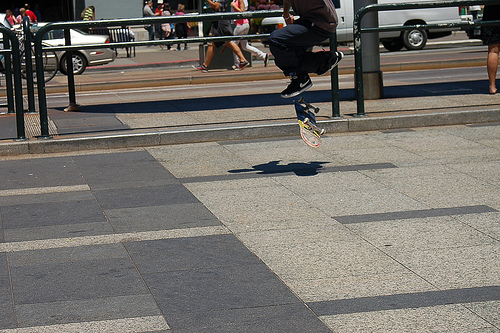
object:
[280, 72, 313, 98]
black shoe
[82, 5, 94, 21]
shirt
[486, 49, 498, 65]
calve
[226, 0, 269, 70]
person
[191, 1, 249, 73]
person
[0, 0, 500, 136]
railing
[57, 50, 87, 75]
tire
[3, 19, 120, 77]
sedan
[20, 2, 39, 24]
person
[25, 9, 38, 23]
red top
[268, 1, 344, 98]
man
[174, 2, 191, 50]
woman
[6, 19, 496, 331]
ground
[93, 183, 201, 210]
tile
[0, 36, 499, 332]
road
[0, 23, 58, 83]
bike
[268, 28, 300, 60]
knee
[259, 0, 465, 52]
truck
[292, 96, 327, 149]
skateboard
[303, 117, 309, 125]
wheel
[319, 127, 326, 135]
wheel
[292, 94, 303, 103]
wheel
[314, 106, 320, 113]
wheel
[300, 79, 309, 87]
nike emblem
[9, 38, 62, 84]
tire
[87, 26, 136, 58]
bench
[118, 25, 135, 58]
person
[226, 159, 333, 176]
shadow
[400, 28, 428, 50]
tire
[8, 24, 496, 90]
street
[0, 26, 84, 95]
street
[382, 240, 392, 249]
spot